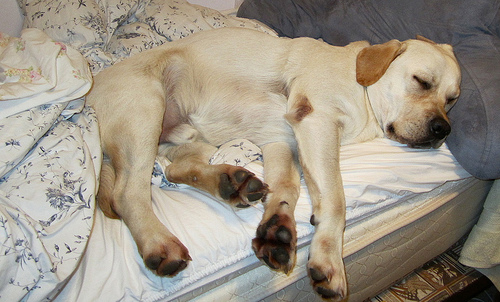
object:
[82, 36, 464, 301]
dog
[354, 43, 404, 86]
ear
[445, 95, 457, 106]
eyes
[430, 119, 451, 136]
nose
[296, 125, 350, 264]
legs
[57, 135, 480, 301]
mattress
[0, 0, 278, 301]
comforter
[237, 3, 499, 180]
pillow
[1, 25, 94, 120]
blanket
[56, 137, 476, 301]
sheet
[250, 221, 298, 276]
paw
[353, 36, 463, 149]
head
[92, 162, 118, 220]
tail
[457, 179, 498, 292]
towel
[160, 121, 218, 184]
leg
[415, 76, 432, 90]
eye